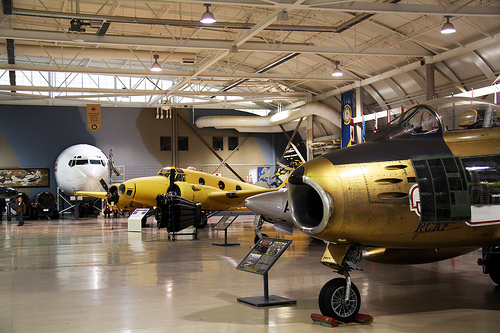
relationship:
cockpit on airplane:
[53, 141, 141, 181] [32, 115, 122, 253]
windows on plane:
[162, 155, 282, 205] [70, 110, 366, 254]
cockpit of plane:
[136, 149, 203, 196] [76, 131, 296, 321]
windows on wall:
[139, 119, 280, 184] [104, 101, 305, 244]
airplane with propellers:
[77, 165, 291, 241] [100, 174, 178, 208]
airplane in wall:
[55, 140, 113, 220] [0, 103, 272, 191]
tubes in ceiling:
[193, 101, 343, 133] [2, 4, 480, 134]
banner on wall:
[84, 100, 102, 132] [2, 92, 285, 204]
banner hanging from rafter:
[336, 84, 362, 151] [35, 58, 364, 95]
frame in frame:
[0, 164, 52, 189] [0, 164, 52, 189]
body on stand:
[49, 144, 120, 195] [52, 185, 109, 218]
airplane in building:
[79, 169, 290, 233] [2, 4, 482, 327]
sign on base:
[235, 234, 294, 273] [238, 273, 298, 306]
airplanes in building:
[55, 98, 484, 318] [0, 0, 500, 333]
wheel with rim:
[315, 275, 363, 321] [331, 290, 358, 315]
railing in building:
[2, 3, 482, 98] [0, 0, 500, 333]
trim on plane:
[272, 173, 338, 221] [246, 92, 484, 317]